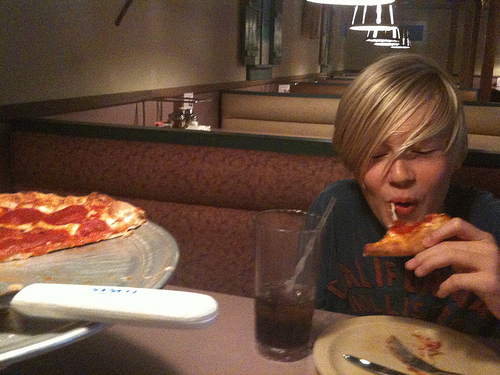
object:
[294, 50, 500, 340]
boy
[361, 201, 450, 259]
pizza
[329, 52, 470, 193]
hair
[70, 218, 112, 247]
pepperonis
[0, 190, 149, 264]
pizza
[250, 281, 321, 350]
drink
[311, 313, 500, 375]
plate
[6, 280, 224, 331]
handle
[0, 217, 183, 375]
platter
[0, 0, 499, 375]
pizza parlor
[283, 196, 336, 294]
straw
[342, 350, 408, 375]
utensils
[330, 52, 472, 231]
head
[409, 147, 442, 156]
eye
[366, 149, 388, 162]
eye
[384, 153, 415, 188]
nose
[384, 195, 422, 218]
mouth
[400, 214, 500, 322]
hand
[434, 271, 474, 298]
finger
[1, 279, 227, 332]
pizza server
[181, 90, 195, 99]
condiments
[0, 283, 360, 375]
table